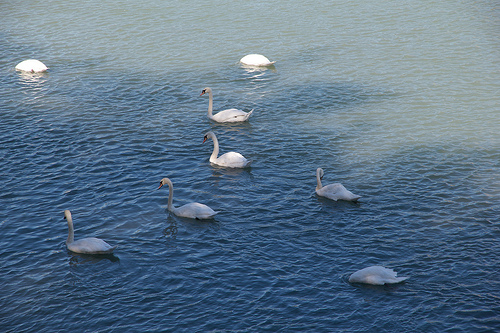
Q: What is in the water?
A: Ducks.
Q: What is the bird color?
A: White.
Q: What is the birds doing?
A: Swimming in water.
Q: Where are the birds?
A: In water.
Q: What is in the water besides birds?
A: Ripples.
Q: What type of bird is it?
A: Swan.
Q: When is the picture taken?
A: Daytime.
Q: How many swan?
A: 8.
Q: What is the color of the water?
A: Blue.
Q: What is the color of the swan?
A: White.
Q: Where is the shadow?
A: In the water.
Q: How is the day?
A: Sunny.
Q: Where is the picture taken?
A: In a lake.